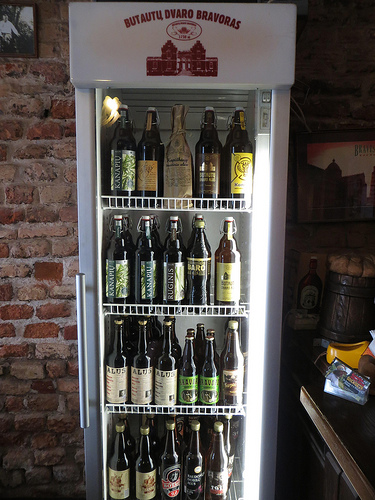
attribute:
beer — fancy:
[212, 216, 258, 308]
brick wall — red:
[3, 55, 82, 498]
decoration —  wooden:
[318, 256, 373, 351]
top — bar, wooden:
[288, 337, 371, 484]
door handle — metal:
[75, 273, 90, 428]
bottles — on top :
[100, 98, 252, 498]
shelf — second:
[103, 300, 244, 317]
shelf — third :
[106, 403, 243, 415]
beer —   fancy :
[224, 106, 265, 204]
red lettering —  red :
[123, 16, 240, 76]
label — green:
[197, 373, 220, 406]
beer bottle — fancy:
[131, 318, 155, 403]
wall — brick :
[3, 61, 77, 181]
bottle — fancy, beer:
[154, 318, 179, 406]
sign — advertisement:
[301, 136, 374, 219]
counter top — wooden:
[280, 345, 374, 497]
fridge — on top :
[68, 1, 297, 498]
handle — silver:
[72, 267, 100, 430]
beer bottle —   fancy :
[107, 104, 138, 196]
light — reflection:
[102, 94, 118, 130]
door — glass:
[80, 87, 257, 497]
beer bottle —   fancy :
[102, 207, 134, 311]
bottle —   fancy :
[194, 101, 220, 200]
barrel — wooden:
[314, 262, 374, 346]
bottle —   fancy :
[137, 106, 164, 204]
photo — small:
[0, 1, 39, 58]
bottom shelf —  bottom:
[106, 411, 250, 498]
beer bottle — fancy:
[116, 189, 239, 349]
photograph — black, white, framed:
[2, 0, 33, 63]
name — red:
[120, 8, 243, 79]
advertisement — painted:
[119, 8, 242, 82]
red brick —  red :
[31, 262, 62, 280]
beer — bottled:
[107, 419, 130, 498]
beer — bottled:
[132, 421, 155, 496]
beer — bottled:
[156, 415, 182, 496]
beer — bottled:
[182, 416, 206, 499]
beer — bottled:
[201, 417, 229, 498]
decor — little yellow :
[318, 326, 368, 371]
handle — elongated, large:
[74, 272, 89, 428]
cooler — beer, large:
[65, 1, 296, 499]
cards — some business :
[328, 358, 371, 390]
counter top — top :
[286, 342, 373, 478]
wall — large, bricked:
[3, 62, 76, 489]